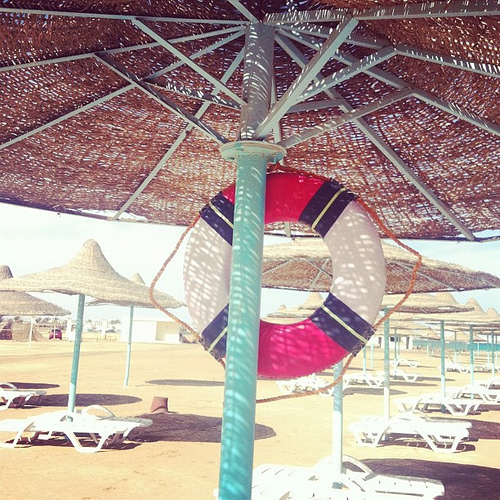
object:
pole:
[331, 357, 344, 474]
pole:
[123, 305, 134, 385]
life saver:
[181, 171, 389, 381]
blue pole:
[439, 320, 445, 377]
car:
[48, 327, 63, 339]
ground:
[0, 330, 500, 497]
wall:
[122, 317, 157, 343]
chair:
[398, 389, 498, 415]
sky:
[0, 202, 499, 322]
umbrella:
[0, 239, 182, 442]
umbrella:
[0, 0, 499, 498]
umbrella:
[261, 235, 499, 488]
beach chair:
[347, 411, 474, 451]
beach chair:
[212, 472, 445, 498]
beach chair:
[0, 410, 143, 454]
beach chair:
[0, 387, 30, 410]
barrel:
[150, 395, 171, 410]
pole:
[382, 310, 389, 430]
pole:
[490, 332, 494, 367]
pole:
[67, 294, 84, 422]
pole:
[218, 27, 275, 499]